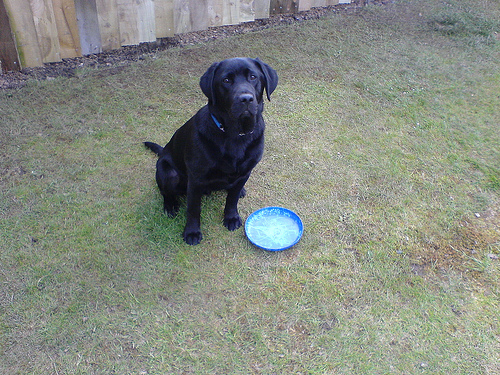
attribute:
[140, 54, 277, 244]
dog — black, sitting, playing, lab, large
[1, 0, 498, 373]
grass — patchy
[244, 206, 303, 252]
frisbee — blue, bowl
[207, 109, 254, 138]
collar — blue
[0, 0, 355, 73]
fence — wood, wooden, brown, aged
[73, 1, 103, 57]
wood plank — unmatched